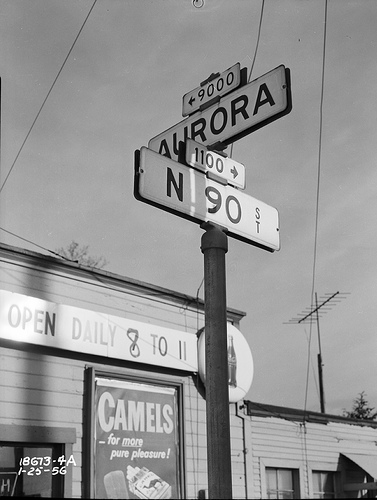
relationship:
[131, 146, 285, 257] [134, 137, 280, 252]
n 90 on sign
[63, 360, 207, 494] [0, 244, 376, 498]
poster on building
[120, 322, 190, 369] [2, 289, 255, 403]
hours on sign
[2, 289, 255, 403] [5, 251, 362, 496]
sign on store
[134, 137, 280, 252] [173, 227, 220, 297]
sign on pole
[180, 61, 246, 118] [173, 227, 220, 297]
street sign on pole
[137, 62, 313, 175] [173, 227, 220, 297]
sign on pole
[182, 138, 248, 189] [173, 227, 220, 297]
signs on pole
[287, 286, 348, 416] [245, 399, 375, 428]
antenna on roof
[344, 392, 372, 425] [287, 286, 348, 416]
tree near antenna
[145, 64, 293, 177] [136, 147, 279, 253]
aurora street on corner with n 90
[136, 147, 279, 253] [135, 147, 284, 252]
n 90 on sign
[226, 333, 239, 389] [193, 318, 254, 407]
cola bottle on sign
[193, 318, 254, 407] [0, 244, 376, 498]
sign on building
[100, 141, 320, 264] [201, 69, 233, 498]
sign on pole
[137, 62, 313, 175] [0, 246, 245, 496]
sign on wall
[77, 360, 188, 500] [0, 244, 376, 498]
poster on building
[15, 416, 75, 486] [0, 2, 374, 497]
number on photo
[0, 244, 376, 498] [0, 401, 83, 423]
building with siding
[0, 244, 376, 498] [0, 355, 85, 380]
building with siding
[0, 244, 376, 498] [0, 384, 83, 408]
building with siding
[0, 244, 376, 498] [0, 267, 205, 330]
building with siding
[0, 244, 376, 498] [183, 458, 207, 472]
building with siding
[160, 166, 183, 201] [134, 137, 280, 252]
letter on sign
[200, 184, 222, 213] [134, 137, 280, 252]
letter on sign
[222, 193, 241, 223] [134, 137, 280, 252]
letter on sign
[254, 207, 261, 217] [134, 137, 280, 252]
letter on sign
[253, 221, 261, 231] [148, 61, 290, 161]
letter on sign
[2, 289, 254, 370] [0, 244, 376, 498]
sign on building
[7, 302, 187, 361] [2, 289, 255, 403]
letters on sign